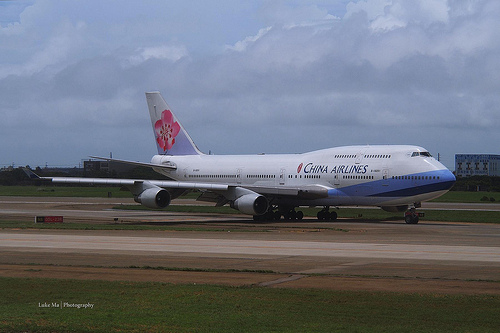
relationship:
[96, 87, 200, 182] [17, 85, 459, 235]
tail of airplane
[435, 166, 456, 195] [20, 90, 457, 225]
nose of airplane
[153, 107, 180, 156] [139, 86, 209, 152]
flower on tail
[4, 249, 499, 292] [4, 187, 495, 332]
dirt on ground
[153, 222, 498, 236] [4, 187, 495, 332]
dirt on ground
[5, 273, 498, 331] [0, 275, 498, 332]
grass on ground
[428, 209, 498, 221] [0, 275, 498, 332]
grass on ground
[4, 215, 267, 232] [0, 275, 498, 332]
grass on ground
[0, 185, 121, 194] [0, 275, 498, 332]
grass on ground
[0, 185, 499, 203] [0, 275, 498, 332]
grass on ground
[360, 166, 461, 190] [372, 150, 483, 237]
stripe on nose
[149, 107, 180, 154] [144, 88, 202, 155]
flower on tail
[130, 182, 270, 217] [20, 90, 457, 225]
engines on airplane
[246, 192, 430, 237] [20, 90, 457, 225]
wheels on airplane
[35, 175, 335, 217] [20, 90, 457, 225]
wing on airplane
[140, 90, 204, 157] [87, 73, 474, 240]
tail of airplane